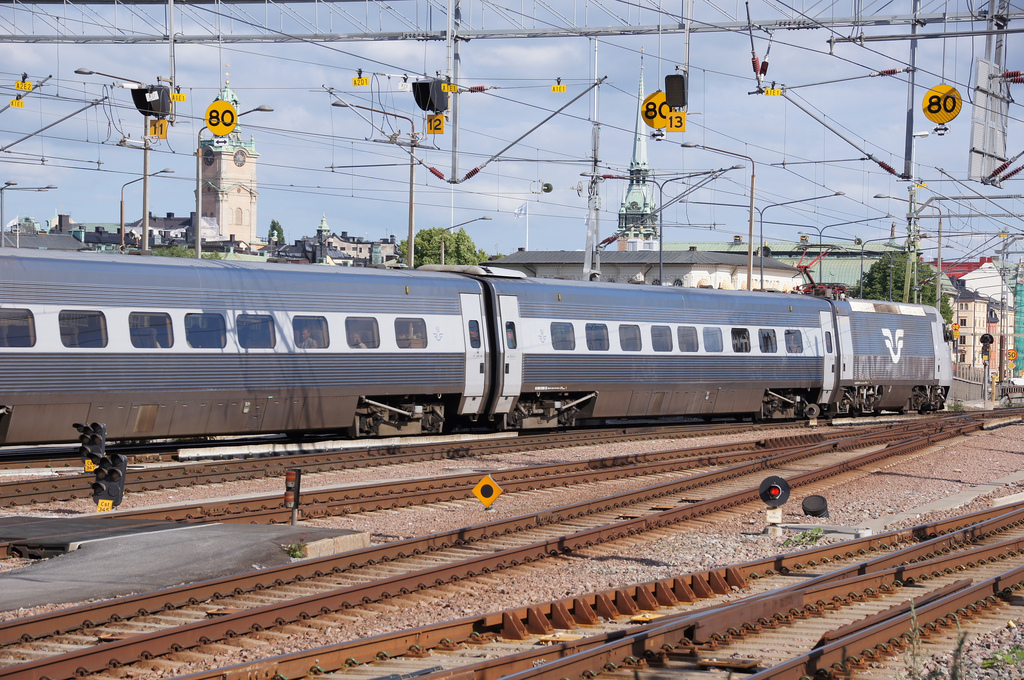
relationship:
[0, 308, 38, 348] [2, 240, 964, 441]
window on a train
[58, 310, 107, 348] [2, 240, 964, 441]
window on a train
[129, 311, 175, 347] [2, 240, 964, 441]
window on a train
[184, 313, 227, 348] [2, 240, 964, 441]
window on a train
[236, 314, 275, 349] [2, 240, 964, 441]
window on a train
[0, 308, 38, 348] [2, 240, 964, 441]
window on a silver train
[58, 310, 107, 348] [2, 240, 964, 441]
window on a silver train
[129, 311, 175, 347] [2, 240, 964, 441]
window on a silver train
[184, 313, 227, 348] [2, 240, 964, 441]
window on a silver train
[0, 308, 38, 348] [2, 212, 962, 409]
window on a train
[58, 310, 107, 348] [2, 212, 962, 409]
window on a train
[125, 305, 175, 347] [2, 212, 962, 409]
window on a train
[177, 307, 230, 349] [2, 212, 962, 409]
window on a train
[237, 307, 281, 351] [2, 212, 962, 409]
window on a train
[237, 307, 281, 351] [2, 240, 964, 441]
window on a silver train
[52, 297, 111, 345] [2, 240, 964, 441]
window on a train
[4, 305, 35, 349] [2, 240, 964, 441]
window on a silver train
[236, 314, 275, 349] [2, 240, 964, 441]
window on a silver train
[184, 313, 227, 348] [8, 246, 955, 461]
window on train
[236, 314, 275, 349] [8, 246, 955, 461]
window on train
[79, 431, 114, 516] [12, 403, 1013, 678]
signal on tracks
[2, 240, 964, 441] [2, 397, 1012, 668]
train on track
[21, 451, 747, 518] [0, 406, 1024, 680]
gravel between track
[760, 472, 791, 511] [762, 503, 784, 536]
light on post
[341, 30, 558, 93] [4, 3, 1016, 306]
cloud in sky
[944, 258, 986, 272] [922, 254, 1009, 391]
roof on building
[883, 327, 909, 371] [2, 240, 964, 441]
logo on train